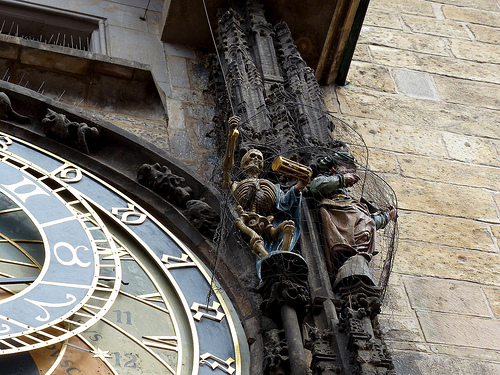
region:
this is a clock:
[0, 139, 226, 372]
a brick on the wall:
[401, 268, 498, 320]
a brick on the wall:
[394, 152, 499, 191]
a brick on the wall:
[412, 303, 499, 352]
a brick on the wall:
[388, 236, 497, 279]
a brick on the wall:
[382, 180, 499, 218]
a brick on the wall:
[428, 49, 498, 81]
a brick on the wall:
[328, 88, 443, 130]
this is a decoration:
[34, 15, 461, 367]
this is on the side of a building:
[26, 35, 452, 336]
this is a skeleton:
[209, 125, 316, 263]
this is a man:
[302, 133, 385, 294]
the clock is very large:
[12, 136, 203, 373]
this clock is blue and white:
[2, 149, 109, 353]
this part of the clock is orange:
[45, 342, 107, 369]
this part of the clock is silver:
[82, 286, 188, 370]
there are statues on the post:
[212, 60, 435, 292]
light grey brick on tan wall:
[387, 62, 440, 104]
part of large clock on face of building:
[0, 133, 253, 374]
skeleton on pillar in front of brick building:
[218, 114, 317, 282]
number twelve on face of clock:
[109, 346, 149, 371]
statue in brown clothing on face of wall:
[307, 150, 400, 293]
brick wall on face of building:
[371, 0, 498, 373]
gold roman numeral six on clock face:
[137, 323, 184, 365]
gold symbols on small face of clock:
[1, 163, 124, 358]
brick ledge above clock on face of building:
[1, 33, 168, 127]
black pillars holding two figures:
[211, 5, 382, 373]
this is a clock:
[3, 203, 155, 335]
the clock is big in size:
[2, 207, 152, 349]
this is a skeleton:
[223, 132, 317, 274]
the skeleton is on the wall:
[233, 174, 282, 223]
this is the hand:
[217, 120, 246, 180]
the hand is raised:
[215, 113, 245, 173]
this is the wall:
[412, 39, 479, 121]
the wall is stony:
[396, 52, 476, 164]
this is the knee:
[277, 217, 301, 238]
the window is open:
[31, 11, 87, 62]